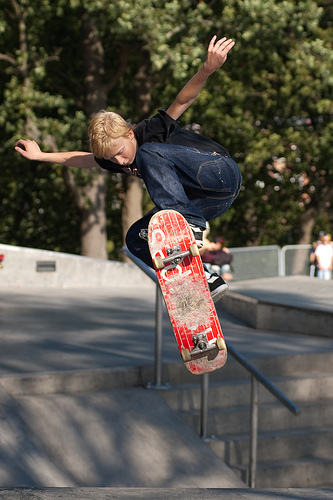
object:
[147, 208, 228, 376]
skateboard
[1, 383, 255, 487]
ramp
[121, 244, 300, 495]
rail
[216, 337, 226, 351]
wheels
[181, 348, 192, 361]
wheels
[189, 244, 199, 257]
wheels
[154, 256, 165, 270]
wheels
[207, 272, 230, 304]
shoe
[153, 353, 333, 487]
steps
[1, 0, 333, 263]
trees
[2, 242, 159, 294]
wall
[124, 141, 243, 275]
jeans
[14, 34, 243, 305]
boy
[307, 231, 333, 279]
person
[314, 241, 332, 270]
shirt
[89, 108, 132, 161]
hair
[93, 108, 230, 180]
t-shirt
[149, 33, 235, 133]
arms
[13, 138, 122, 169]
arms